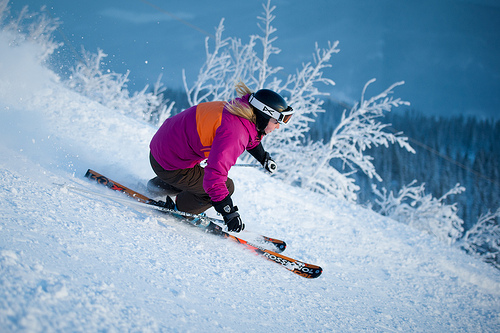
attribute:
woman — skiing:
[146, 78, 295, 236]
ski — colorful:
[78, 165, 325, 280]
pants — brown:
[146, 150, 237, 214]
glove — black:
[205, 196, 263, 227]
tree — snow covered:
[312, 61, 416, 211]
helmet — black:
[238, 77, 336, 152]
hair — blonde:
[223, 86, 276, 138]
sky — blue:
[31, 2, 498, 112]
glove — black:
[260, 150, 277, 175]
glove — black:
[214, 202, 245, 234]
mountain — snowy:
[148, 83, 499, 262]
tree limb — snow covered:
[182, 3, 417, 206]